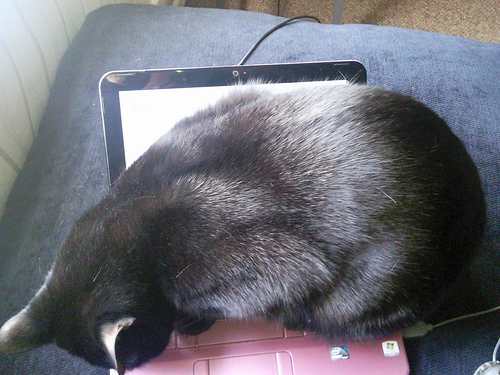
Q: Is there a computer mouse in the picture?
A: Yes, there is a computer mouse.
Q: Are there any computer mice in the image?
A: Yes, there is a computer mouse.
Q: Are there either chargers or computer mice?
A: Yes, there is a computer mouse.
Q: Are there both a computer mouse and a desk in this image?
A: No, there is a computer mouse but no desks.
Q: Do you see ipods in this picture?
A: No, there are no ipods.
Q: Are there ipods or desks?
A: No, there are no ipods or desks.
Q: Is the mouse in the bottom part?
A: Yes, the mouse is in the bottom of the image.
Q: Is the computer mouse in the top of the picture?
A: No, the computer mouse is in the bottom of the image.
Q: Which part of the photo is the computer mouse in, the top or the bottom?
A: The computer mouse is in the bottom of the image.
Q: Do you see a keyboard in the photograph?
A: Yes, there is a keyboard.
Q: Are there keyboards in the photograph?
A: Yes, there is a keyboard.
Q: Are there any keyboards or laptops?
A: Yes, there is a keyboard.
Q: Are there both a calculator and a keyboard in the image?
A: No, there is a keyboard but no calculators.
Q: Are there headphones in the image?
A: No, there are no headphones.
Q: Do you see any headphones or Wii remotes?
A: No, there are no headphones or Wii remotes.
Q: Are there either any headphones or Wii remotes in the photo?
A: No, there are no headphones or Wii remotes.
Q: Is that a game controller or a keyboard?
A: That is a keyboard.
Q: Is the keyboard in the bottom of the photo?
A: Yes, the keyboard is in the bottom of the image.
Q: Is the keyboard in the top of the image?
A: No, the keyboard is in the bottom of the image.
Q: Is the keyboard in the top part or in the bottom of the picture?
A: The keyboard is in the bottom of the image.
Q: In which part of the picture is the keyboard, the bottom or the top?
A: The keyboard is in the bottom of the image.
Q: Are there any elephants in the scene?
A: No, there are no elephants.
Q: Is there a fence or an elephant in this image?
A: No, there are no elephants or fences.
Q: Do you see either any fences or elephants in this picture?
A: No, there are no elephants or fences.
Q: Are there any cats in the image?
A: Yes, there is a cat.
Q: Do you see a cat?
A: Yes, there is a cat.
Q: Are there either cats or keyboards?
A: Yes, there is a cat.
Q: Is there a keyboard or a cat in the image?
A: Yes, there is a cat.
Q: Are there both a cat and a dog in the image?
A: No, there is a cat but no dogs.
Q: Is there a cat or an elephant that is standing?
A: Yes, the cat is standing.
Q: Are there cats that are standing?
A: Yes, there is a cat that is standing.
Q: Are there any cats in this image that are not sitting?
A: Yes, there is a cat that is standing.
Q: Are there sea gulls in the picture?
A: No, there are no sea gulls.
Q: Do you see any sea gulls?
A: No, there are no sea gulls.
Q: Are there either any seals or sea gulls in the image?
A: No, there are no sea gulls or seals.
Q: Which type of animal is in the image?
A: The animal is a cat.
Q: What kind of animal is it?
A: The animal is a cat.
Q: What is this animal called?
A: That is a cat.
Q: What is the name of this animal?
A: That is a cat.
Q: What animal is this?
A: That is a cat.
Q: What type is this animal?
A: That is a cat.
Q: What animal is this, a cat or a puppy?
A: That is a cat.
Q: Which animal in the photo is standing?
A: The animal is a cat.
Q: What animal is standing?
A: The animal is a cat.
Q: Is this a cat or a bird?
A: This is a cat.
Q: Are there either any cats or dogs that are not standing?
A: No, there is a cat but it is standing.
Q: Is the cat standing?
A: Yes, the cat is standing.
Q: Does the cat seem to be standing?
A: Yes, the cat is standing.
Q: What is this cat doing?
A: The cat is standing.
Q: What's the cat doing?
A: The cat is standing.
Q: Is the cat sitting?
A: No, the cat is standing.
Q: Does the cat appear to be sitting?
A: No, the cat is standing.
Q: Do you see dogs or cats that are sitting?
A: No, there is a cat but it is standing.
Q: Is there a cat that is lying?
A: No, there is a cat but it is standing.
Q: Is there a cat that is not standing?
A: No, there is a cat but it is standing.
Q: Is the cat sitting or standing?
A: The cat is standing.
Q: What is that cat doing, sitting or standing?
A: The cat is standing.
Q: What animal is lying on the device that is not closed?
A: The cat is lying on the laptop.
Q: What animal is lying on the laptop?
A: The cat is lying on the laptop.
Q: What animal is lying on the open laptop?
A: The animal is a cat.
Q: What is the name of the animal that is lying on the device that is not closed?
A: The animal is a cat.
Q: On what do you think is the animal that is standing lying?
A: The cat is lying on the laptop.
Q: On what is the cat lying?
A: The cat is lying on the laptop.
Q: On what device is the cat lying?
A: The cat is lying on the laptop.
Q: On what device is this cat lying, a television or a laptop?
A: The cat is lying on a laptop.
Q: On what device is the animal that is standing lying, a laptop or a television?
A: The cat is lying on a laptop.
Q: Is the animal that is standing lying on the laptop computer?
A: Yes, the cat is lying on the laptop computer.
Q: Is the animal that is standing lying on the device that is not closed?
A: Yes, the cat is lying on the laptop computer.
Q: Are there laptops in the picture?
A: Yes, there is a laptop.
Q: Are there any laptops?
A: Yes, there is a laptop.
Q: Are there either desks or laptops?
A: Yes, there is a laptop.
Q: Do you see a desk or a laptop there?
A: Yes, there is a laptop.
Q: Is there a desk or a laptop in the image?
A: Yes, there is a laptop.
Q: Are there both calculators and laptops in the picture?
A: No, there is a laptop but no calculators.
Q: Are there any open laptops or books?
A: Yes, there is an open laptop.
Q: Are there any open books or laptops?
A: Yes, there is an open laptop.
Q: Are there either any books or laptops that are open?
A: Yes, the laptop is open.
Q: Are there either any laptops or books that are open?
A: Yes, the laptop is open.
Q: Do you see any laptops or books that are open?
A: Yes, the laptop is open.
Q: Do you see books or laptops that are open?
A: Yes, the laptop is open.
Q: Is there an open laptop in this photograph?
A: Yes, there is an open laptop.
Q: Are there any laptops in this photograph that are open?
A: Yes, there is a laptop that is open.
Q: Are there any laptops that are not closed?
A: Yes, there is a open laptop.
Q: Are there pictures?
A: No, there are no pictures.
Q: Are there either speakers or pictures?
A: No, there are no pictures or speakers.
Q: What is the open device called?
A: The device is a laptop.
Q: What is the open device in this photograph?
A: The device is a laptop.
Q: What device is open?
A: The device is a laptop.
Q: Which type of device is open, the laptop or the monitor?
A: The laptop is open.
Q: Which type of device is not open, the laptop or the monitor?
A: The monitor is not open.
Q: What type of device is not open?
A: The device is a monitor.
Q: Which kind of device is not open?
A: The device is a monitor.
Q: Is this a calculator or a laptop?
A: This is a laptop.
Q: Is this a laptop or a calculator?
A: This is a laptop.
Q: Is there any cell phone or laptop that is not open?
A: No, there is a laptop but it is open.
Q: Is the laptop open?
A: Yes, the laptop is open.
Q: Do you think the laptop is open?
A: Yes, the laptop is open.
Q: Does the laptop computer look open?
A: Yes, the laptop computer is open.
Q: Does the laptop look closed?
A: No, the laptop is open.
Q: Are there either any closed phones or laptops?
A: No, there is a laptop but it is open.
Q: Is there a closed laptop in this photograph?
A: No, there is a laptop but it is open.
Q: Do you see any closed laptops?
A: No, there is a laptop but it is open.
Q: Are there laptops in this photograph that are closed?
A: No, there is a laptop but it is open.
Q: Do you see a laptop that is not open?
A: No, there is a laptop but it is open.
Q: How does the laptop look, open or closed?
A: The laptop is open.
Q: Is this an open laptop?
A: Yes, this is an open laptop.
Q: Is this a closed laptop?
A: No, this is an open laptop.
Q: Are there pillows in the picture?
A: Yes, there is a pillow.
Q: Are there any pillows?
A: Yes, there is a pillow.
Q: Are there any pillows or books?
A: Yes, there is a pillow.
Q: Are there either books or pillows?
A: Yes, there is a pillow.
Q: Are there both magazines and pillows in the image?
A: No, there is a pillow but no magazines.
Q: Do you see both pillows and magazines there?
A: No, there is a pillow but no magazines.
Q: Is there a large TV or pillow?
A: Yes, there is a large pillow.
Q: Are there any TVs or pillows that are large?
A: Yes, the pillow is large.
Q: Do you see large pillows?
A: Yes, there is a large pillow.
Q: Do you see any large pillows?
A: Yes, there is a large pillow.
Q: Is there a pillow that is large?
A: Yes, there is a pillow that is large.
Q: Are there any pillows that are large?
A: Yes, there is a pillow that is large.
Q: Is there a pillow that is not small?
A: Yes, there is a large pillow.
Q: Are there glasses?
A: No, there are no glasses.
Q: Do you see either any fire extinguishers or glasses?
A: No, there are no glasses or fire extinguishers.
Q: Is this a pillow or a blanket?
A: This is a pillow.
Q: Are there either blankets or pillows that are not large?
A: No, there is a pillow but it is large.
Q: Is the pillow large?
A: Yes, the pillow is large.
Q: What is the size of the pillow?
A: The pillow is large.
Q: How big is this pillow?
A: The pillow is large.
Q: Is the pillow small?
A: No, the pillow is large.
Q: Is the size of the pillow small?
A: No, the pillow is large.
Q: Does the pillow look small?
A: No, the pillow is large.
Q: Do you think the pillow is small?
A: No, the pillow is large.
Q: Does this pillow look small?
A: No, the pillow is large.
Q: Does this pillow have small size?
A: No, the pillow is large.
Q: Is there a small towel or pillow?
A: No, there is a pillow but it is large.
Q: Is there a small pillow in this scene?
A: No, there is a pillow but it is large.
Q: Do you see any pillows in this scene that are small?
A: No, there is a pillow but it is large.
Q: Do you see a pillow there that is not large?
A: No, there is a pillow but it is large.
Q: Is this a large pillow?
A: Yes, this is a large pillow.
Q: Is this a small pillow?
A: No, this is a large pillow.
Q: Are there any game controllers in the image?
A: No, there are no game controllers.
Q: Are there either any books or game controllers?
A: No, there are no game controllers or books.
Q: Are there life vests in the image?
A: No, there are no life vests.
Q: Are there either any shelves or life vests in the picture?
A: No, there are no life vests or shelves.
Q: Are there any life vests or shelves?
A: No, there are no life vests or shelves.